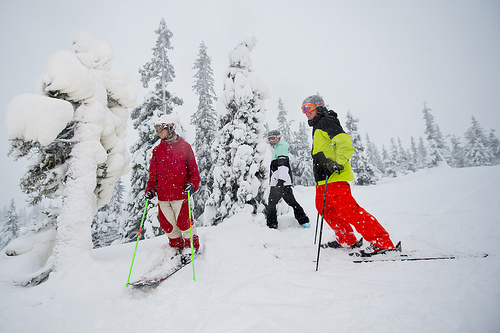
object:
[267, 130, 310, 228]
man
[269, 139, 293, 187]
jacket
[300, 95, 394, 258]
skier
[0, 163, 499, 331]
hill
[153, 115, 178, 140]
helmet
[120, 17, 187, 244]
trees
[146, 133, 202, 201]
jacket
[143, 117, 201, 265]
boy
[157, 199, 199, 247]
pants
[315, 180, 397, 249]
pants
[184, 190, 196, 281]
ski stick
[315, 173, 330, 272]
ski stick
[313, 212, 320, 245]
ski stick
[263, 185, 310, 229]
black pants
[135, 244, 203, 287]
skis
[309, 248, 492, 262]
skis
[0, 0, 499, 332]
snow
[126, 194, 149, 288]
stick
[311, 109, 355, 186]
jacket